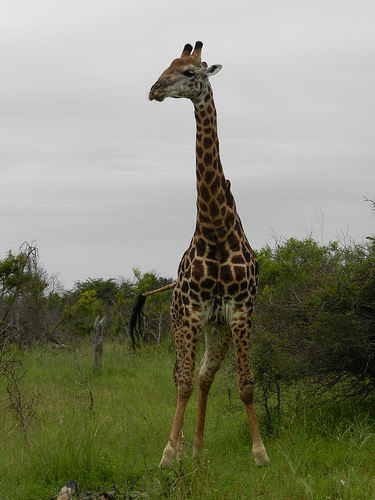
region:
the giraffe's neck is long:
[145, 65, 270, 250]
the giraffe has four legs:
[148, 313, 279, 479]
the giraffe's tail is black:
[111, 275, 149, 351]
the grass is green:
[46, 413, 150, 467]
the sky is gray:
[58, 192, 128, 254]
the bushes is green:
[39, 271, 114, 317]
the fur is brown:
[176, 189, 228, 269]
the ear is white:
[180, 52, 237, 90]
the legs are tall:
[159, 326, 296, 489]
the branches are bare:
[4, 316, 87, 363]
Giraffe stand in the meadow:
[125, 31, 277, 485]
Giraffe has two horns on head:
[177, 33, 205, 63]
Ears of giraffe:
[201, 60, 225, 78]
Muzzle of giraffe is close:
[143, 76, 167, 103]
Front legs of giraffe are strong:
[138, 300, 286, 487]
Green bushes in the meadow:
[261, 240, 369, 367]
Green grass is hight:
[15, 345, 161, 492]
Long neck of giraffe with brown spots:
[183, 91, 246, 244]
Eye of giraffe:
[179, 60, 200, 79]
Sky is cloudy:
[1, 8, 146, 267]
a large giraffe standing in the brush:
[123, 36, 318, 474]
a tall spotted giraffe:
[111, 25, 302, 489]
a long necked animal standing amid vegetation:
[124, 20, 287, 493]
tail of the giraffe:
[121, 271, 177, 347]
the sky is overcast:
[7, 25, 136, 250]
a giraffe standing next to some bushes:
[89, 22, 365, 437]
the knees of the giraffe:
[172, 376, 274, 404]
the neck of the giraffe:
[185, 106, 236, 235]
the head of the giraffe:
[137, 32, 224, 117]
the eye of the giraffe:
[179, 68, 198, 80]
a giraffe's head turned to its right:
[144, 36, 228, 106]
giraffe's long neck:
[178, 101, 261, 242]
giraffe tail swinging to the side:
[119, 265, 188, 353]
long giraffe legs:
[151, 301, 287, 474]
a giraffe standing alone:
[5, 19, 372, 495]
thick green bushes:
[265, 256, 371, 441]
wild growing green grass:
[5, 320, 150, 466]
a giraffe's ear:
[204, 58, 224, 79]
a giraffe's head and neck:
[126, 28, 282, 241]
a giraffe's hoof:
[240, 444, 281, 470]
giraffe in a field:
[134, 41, 275, 469]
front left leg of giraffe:
[222, 296, 272, 470]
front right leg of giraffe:
[161, 304, 207, 478]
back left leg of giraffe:
[193, 324, 227, 462]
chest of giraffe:
[178, 240, 258, 302]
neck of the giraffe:
[190, 98, 233, 241]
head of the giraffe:
[148, 38, 223, 103]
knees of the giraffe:
[169, 364, 258, 403]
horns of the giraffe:
[177, 39, 205, 57]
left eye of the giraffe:
[180, 66, 200, 78]